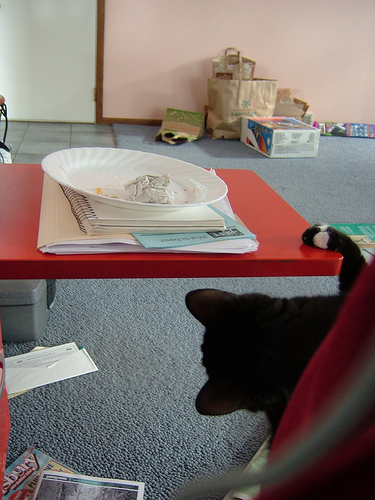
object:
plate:
[39, 147, 231, 213]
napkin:
[125, 167, 174, 204]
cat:
[188, 221, 370, 420]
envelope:
[2, 346, 99, 399]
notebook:
[62, 182, 227, 237]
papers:
[40, 232, 250, 266]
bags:
[206, 72, 279, 143]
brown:
[214, 87, 242, 107]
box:
[241, 115, 320, 158]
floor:
[4, 111, 375, 500]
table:
[0, 160, 345, 283]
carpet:
[279, 137, 373, 227]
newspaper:
[327, 217, 374, 255]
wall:
[104, 2, 374, 135]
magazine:
[3, 442, 156, 499]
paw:
[303, 219, 340, 253]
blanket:
[262, 239, 375, 500]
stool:
[0, 90, 19, 167]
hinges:
[93, 86, 98, 103]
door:
[0, 3, 102, 127]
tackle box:
[0, 275, 59, 340]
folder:
[36, 166, 134, 258]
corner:
[291, 237, 353, 275]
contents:
[6, 341, 79, 368]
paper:
[140, 227, 252, 248]